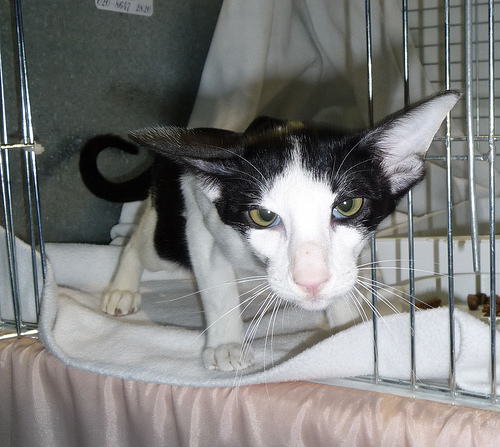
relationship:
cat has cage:
[76, 96, 482, 372] [2, 2, 498, 396]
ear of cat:
[358, 65, 445, 205] [76, 96, 482, 372]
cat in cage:
[76, 96, 473, 362] [2, 2, 498, 396]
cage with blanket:
[2, 2, 498, 396] [28, 220, 497, 419]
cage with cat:
[2, 2, 498, 396] [76, 96, 482, 372]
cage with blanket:
[2, 2, 498, 396] [272, 303, 498, 385]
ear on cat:
[120, 117, 256, 178] [78, 66, 477, 352]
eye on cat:
[241, 197, 283, 231] [76, 96, 482, 372]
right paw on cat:
[204, 341, 254, 373] [76, 96, 482, 372]